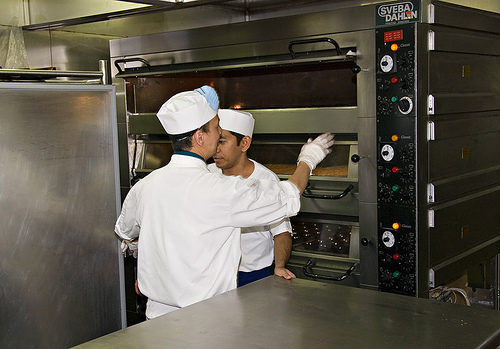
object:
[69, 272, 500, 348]
table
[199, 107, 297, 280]
person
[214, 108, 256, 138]
hat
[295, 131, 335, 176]
glove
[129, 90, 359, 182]
cook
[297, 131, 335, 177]
hands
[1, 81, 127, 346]
door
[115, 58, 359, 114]
window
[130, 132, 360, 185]
window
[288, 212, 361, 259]
window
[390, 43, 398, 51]
light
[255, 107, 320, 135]
wall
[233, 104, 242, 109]
light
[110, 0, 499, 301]
appliance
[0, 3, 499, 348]
restaurant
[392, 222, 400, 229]
amber light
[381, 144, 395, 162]
knob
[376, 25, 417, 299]
controls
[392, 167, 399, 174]
button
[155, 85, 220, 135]
hat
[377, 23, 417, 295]
knobs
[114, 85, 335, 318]
baker